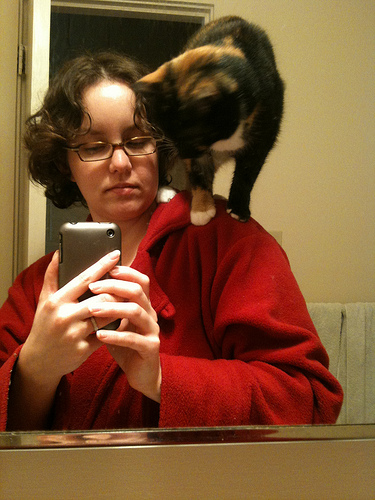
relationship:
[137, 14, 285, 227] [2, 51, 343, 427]
cat on shoulder of woman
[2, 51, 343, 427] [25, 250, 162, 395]
woman has hands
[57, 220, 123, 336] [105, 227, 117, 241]
smartphone has camera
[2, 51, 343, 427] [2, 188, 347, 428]
woman wearing robe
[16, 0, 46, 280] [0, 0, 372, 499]
door to bathroom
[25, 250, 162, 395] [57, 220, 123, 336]
hands holding smartphone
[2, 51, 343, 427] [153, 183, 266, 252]
woman has shoulder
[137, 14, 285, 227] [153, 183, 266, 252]
cat on top of shoulder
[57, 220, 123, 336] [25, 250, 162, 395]
smartphone held by hands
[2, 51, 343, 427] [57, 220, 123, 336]
woman looking down at smartphone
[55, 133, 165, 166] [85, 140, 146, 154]
glasses over eyes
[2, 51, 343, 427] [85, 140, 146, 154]
woman has eyes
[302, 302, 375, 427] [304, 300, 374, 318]
towel hanging from rack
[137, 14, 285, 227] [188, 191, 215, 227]
cat has paw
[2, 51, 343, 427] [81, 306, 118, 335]
woman has finger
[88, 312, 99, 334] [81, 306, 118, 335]
ring worn on finger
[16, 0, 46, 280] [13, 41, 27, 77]
door has hinge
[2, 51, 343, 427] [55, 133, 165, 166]
woman wearing glasses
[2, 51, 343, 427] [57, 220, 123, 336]
woman holding smartphone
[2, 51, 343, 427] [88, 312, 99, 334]
woman wearing ring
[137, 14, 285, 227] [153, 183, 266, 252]
cat sitting on top of shoulder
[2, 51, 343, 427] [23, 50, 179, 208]
woman has hair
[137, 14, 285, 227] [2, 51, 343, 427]
cat looking at woman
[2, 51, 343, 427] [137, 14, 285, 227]
woman taking picture with cat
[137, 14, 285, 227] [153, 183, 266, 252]
cat perched on shoulder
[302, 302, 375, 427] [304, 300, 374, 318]
towel hanging on rack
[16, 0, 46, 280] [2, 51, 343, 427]
door behind woman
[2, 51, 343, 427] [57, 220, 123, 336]
woman taking pictures with smartphone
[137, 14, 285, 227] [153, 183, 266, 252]
cat looking down from shoulder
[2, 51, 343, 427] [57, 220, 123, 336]
woman looking at smartphone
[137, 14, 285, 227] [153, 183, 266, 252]
cat sitting on shoulder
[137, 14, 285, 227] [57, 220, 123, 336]
cat looking down at smartphone